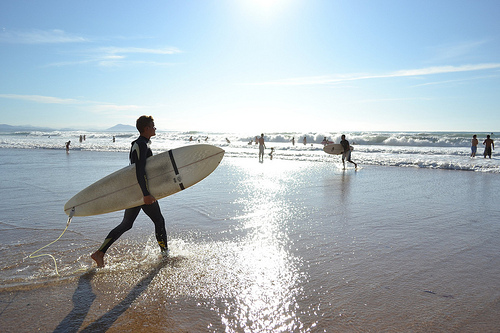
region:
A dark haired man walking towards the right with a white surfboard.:
[90, 114, 172, 270]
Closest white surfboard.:
[62, 143, 224, 218]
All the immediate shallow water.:
[3, 152, 498, 330]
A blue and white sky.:
[1, 2, 496, 133]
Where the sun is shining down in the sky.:
[235, 2, 294, 19]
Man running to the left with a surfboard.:
[340, 134, 357, 171]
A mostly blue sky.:
[1, 1, 498, 129]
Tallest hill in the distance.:
[105, 122, 135, 132]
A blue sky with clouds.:
[0, 0, 498, 132]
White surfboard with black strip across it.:
[56, 142, 223, 218]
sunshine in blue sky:
[2, 1, 497, 128]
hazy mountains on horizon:
[0, 121, 175, 133]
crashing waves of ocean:
[0, 131, 497, 172]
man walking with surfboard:
[64, 113, 224, 270]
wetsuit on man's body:
[92, 137, 169, 265]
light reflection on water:
[197, 157, 321, 331]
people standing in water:
[468, 132, 497, 158]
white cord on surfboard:
[26, 206, 75, 281]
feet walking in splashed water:
[89, 211, 184, 269]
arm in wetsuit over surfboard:
[65, 143, 224, 218]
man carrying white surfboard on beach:
[48, 111, 228, 273]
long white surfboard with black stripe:
[54, 142, 231, 222]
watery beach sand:
[13, 150, 480, 322]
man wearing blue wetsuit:
[97, 140, 183, 251]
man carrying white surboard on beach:
[322, 135, 359, 175]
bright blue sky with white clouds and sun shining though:
[6, 3, 498, 128]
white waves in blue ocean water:
[13, 131, 498, 153]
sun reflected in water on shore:
[166, 155, 318, 325]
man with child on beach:
[254, 130, 276, 161]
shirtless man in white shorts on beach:
[255, 133, 267, 163]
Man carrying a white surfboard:
[64, 114, 228, 274]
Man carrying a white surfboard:
[323, 132, 362, 174]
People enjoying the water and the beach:
[48, 124, 498, 269]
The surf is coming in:
[1, 120, 498, 332]